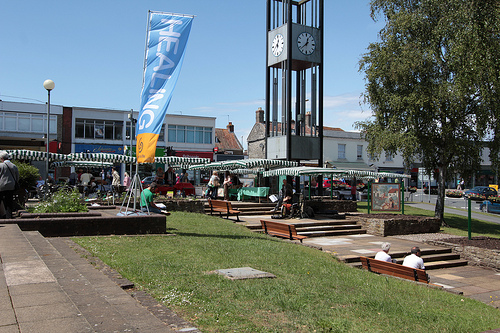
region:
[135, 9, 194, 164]
blue, white, and yellow "healing" sign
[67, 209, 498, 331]
grassy area in park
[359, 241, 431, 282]
two people sitting on wood bench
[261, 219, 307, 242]
wood bench beside sidewalk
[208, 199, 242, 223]
wood bench beside sidewalk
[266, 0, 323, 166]
metal clock tower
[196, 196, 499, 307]
concrete sidewalk with steps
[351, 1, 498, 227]
tree standing in a park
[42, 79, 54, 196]
metal light post with white globe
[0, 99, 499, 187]
buildings lined near park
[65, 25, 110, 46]
this is the sky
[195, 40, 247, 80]
the sky is blue in color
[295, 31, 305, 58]
this is a clock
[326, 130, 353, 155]
this is a building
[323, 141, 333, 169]
this is the wall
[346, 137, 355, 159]
the wall is white in color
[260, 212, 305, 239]
this is a bench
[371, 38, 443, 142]
this is a tree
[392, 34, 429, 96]
the leaves are green in color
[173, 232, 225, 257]
the grass is green in color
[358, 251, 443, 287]
brown wooden bench in a city sitting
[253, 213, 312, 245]
brown wooden bench in a city sitting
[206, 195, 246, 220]
brown wooden bench in a city sitting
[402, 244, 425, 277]
elderly gentleman sitting on wooden bench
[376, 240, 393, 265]
elderly female sitting on wooden bench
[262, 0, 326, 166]
clock tower in the middle of the city square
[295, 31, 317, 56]
round clock on the clock tower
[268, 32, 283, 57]
round clock on the clock tower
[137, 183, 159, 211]
person in green shirt sitting on a stoop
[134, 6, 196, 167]
blue and yellow flag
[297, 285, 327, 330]
part of a ground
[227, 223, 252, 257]
[part of a ground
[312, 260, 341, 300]
par tof a ground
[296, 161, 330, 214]
part of a stand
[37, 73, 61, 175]
a white light in front a building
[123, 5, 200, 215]
a blue and yellow flag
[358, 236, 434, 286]
two people sit in a bench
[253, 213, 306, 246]
a bench of wood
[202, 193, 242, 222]
a bench of wood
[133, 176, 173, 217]
man wearing green shirt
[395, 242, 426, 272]
man with white shirt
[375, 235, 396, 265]
man with white shirt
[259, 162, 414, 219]
the awning is striped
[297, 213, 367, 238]
three steps of stairs